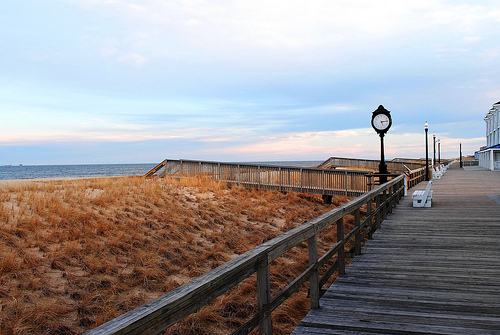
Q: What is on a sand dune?
A: Grass.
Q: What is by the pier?
A: Stairways.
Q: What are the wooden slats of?
A: A boardwalk.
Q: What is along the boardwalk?
A: Railings.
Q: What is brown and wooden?
A: A railing.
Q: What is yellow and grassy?
A: A field.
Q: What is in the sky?
A: Clouds.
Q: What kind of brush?
A: Scrub.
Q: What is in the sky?
A: Clouds.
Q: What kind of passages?
A: Boardwalk.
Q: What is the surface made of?
A: Wood.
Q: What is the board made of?
A: Wood.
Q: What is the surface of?
A: Water.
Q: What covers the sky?
A: Cloud.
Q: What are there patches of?
A: Grass.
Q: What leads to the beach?
A: Ramp.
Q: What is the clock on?
A: A pole.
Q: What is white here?
A: Clouds.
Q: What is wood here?
A: The sidewalk.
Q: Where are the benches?
A: On the sidewalk.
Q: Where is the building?
A: By the sidewalk.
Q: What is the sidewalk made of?
A: Wood.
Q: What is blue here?
A: The sky.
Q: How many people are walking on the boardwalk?
A: None.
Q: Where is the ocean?
A: On the left.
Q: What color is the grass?
A: Brown.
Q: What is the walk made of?
A: Wood.